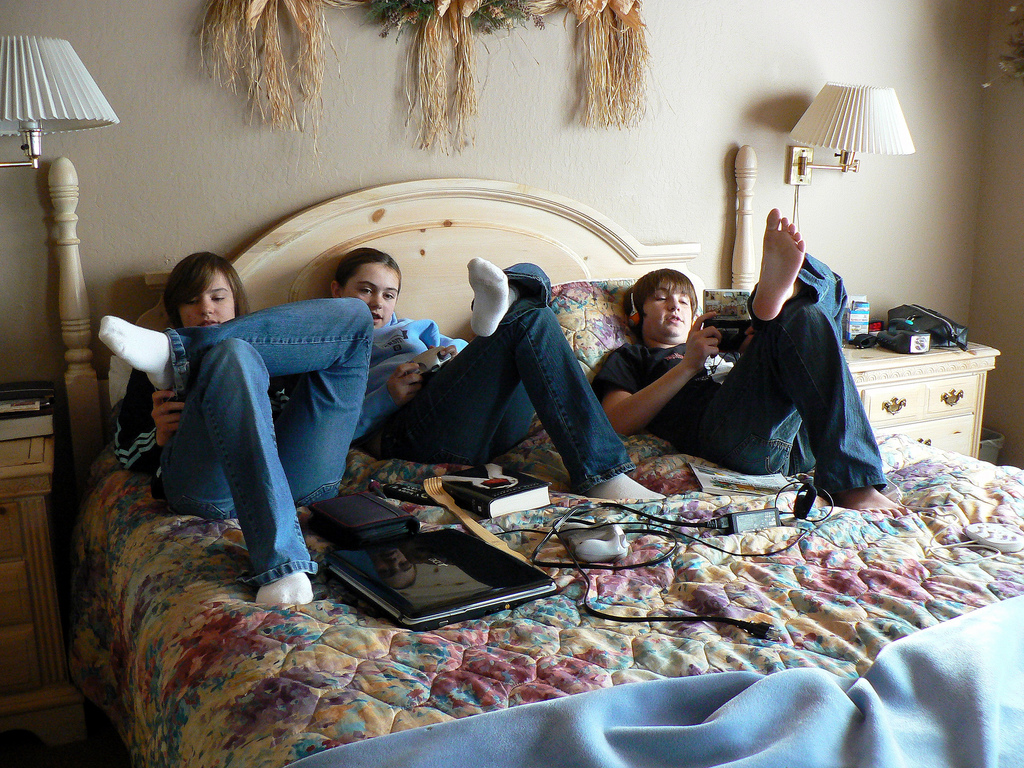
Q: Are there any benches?
A: No, there are no benches.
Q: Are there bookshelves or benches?
A: No, there are no benches or bookshelves.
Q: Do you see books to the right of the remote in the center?
A: Yes, there is a book to the right of the remote.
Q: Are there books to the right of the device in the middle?
A: Yes, there is a book to the right of the remote.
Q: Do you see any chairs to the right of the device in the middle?
A: No, there is a book to the right of the remote.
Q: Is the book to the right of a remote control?
A: Yes, the book is to the right of a remote control.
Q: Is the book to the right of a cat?
A: No, the book is to the right of a remote control.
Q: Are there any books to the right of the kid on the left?
A: Yes, there is a book to the right of the child.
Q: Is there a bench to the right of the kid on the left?
A: No, there is a book to the right of the kid.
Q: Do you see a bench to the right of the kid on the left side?
A: No, there is a book to the right of the kid.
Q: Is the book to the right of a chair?
A: No, the book is to the right of the child.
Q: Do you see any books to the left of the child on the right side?
A: Yes, there is a book to the left of the child.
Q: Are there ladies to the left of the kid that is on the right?
A: No, there is a book to the left of the kid.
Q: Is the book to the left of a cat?
A: No, the book is to the left of the kid.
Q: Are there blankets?
A: Yes, there is a blanket.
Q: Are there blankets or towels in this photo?
A: Yes, there is a blanket.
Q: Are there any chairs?
A: No, there are no chairs.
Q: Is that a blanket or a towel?
A: That is a blanket.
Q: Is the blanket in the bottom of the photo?
A: Yes, the blanket is in the bottom of the image.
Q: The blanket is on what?
A: The blanket is on the bed.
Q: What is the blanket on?
A: The blanket is on the bed.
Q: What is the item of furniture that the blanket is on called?
A: The piece of furniture is a bed.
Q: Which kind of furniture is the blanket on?
A: The blanket is on the bed.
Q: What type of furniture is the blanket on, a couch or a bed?
A: The blanket is on a bed.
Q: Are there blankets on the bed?
A: Yes, there is a blanket on the bed.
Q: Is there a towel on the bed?
A: No, there is a blanket on the bed.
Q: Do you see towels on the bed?
A: No, there is a blanket on the bed.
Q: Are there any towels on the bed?
A: No, there is a blanket on the bed.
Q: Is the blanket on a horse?
A: No, the blanket is on a bed.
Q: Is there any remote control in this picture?
A: Yes, there is a remote control.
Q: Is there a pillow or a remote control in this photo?
A: Yes, there is a remote control.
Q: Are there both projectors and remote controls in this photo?
A: No, there is a remote control but no projectors.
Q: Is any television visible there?
A: No, there are no televisions.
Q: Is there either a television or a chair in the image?
A: No, there are no televisions or chairs.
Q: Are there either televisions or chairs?
A: No, there are no televisions or chairs.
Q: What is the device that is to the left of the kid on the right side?
A: The device is a remote control.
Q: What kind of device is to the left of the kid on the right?
A: The device is a remote control.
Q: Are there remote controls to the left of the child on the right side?
A: Yes, there is a remote control to the left of the child.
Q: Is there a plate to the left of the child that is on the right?
A: No, there is a remote control to the left of the child.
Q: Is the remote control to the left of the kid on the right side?
A: Yes, the remote control is to the left of the kid.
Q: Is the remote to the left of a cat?
A: No, the remote is to the left of the kid.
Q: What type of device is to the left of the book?
A: The device is a remote control.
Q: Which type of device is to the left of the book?
A: The device is a remote control.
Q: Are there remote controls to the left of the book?
A: Yes, there is a remote control to the left of the book.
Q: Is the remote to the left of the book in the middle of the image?
A: Yes, the remote is to the left of the book.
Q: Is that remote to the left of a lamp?
A: No, the remote is to the left of the book.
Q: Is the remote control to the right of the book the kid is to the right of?
A: No, the remote control is to the left of the book.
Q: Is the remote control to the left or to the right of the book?
A: The remote control is to the left of the book.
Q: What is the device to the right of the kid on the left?
A: The device is a remote control.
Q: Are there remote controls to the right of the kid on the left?
A: Yes, there is a remote control to the right of the child.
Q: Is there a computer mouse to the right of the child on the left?
A: No, there is a remote control to the right of the kid.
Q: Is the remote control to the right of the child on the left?
A: Yes, the remote control is to the right of the kid.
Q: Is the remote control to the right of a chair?
A: No, the remote control is to the right of the kid.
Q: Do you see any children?
A: Yes, there is a child.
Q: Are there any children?
A: Yes, there is a child.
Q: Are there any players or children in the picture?
A: Yes, there is a child.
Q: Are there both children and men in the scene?
A: No, there is a child but no men.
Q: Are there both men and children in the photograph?
A: No, there is a child but no men.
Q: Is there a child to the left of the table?
A: Yes, there is a child to the left of the table.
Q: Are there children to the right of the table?
A: No, the child is to the left of the table.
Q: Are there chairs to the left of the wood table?
A: No, there is a child to the left of the table.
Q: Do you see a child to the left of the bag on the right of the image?
A: Yes, there is a child to the left of the bag.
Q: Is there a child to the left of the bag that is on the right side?
A: Yes, there is a child to the left of the bag.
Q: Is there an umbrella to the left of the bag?
A: No, there is a child to the left of the bag.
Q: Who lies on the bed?
A: The kid lies on the bed.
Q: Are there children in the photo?
A: Yes, there is a child.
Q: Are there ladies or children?
A: Yes, there is a child.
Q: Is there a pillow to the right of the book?
A: No, there is a child to the right of the book.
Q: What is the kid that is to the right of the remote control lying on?
A: The kid is lying on the bed.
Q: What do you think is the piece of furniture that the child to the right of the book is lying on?
A: The piece of furniture is a bed.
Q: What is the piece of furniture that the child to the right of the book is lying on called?
A: The piece of furniture is a bed.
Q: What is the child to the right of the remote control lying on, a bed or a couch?
A: The child is lying on a bed.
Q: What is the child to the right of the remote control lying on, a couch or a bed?
A: The child is lying on a bed.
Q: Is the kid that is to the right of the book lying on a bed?
A: Yes, the child is lying on a bed.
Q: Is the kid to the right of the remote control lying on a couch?
A: No, the kid is lying on a bed.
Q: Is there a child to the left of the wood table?
A: Yes, there is a child to the left of the table.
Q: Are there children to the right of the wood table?
A: No, the child is to the left of the table.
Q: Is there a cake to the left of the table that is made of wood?
A: No, there is a child to the left of the table.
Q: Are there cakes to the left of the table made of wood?
A: No, there is a child to the left of the table.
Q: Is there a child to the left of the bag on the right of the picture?
A: Yes, there is a child to the left of the bag.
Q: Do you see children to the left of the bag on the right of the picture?
A: Yes, there is a child to the left of the bag.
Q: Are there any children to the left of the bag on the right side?
A: Yes, there is a child to the left of the bag.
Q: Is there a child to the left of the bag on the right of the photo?
A: Yes, there is a child to the left of the bag.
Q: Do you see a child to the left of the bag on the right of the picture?
A: Yes, there is a child to the left of the bag.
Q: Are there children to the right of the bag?
A: No, the child is to the left of the bag.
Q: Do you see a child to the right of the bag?
A: No, the child is to the left of the bag.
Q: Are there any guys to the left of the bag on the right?
A: No, there is a child to the left of the bag.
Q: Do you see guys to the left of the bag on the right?
A: No, there is a child to the left of the bag.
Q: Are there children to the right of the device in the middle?
A: Yes, there is a child to the right of the remote.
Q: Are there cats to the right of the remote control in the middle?
A: No, there is a child to the right of the remote control.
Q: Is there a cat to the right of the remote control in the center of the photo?
A: No, there is a child to the right of the remote control.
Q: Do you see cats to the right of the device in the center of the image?
A: No, there is a child to the right of the remote control.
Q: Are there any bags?
A: Yes, there is a bag.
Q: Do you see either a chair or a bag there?
A: Yes, there is a bag.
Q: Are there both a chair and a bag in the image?
A: No, there is a bag but no chairs.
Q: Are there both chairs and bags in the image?
A: No, there is a bag but no chairs.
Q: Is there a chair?
A: No, there are no chairs.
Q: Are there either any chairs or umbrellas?
A: No, there are no chairs or umbrellas.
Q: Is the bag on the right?
A: Yes, the bag is on the right of the image.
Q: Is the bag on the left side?
A: No, the bag is on the right of the image.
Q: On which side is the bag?
A: The bag is on the right of the image.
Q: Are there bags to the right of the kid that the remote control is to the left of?
A: Yes, there is a bag to the right of the child.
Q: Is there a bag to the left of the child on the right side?
A: No, the bag is to the right of the child.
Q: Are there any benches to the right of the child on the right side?
A: No, there is a bag to the right of the kid.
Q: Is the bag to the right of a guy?
A: No, the bag is to the right of a child.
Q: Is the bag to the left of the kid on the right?
A: No, the bag is to the right of the kid.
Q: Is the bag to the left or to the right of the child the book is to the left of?
A: The bag is to the right of the child.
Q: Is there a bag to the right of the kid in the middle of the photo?
A: Yes, there is a bag to the right of the child.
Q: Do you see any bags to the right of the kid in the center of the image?
A: Yes, there is a bag to the right of the child.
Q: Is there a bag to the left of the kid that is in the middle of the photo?
A: No, the bag is to the right of the child.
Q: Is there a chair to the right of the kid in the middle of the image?
A: No, there is a bag to the right of the child.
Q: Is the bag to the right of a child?
A: Yes, the bag is to the right of a child.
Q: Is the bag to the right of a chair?
A: No, the bag is to the right of a child.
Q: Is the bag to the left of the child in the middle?
A: No, the bag is to the right of the child.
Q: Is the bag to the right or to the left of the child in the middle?
A: The bag is to the right of the kid.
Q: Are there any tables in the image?
A: Yes, there is a table.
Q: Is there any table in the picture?
A: Yes, there is a table.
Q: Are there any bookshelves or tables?
A: Yes, there is a table.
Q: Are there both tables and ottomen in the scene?
A: No, there is a table but no ottomen.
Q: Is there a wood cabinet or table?
A: Yes, there is a wood table.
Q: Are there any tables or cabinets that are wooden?
A: Yes, the table is wooden.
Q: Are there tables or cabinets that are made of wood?
A: Yes, the table is made of wood.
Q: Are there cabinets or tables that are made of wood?
A: Yes, the table is made of wood.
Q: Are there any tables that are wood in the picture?
A: Yes, there is a wood table.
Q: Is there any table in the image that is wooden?
A: Yes, there is a table that is wooden.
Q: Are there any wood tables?
A: Yes, there is a table that is made of wood.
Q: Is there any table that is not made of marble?
A: Yes, there is a table that is made of wood.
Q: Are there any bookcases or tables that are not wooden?
A: No, there is a table but it is wooden.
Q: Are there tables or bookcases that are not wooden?
A: No, there is a table but it is wooden.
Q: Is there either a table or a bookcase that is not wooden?
A: No, there is a table but it is wooden.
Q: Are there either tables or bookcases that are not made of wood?
A: No, there is a table but it is made of wood.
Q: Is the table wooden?
A: Yes, the table is wooden.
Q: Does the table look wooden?
A: Yes, the table is wooden.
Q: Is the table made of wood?
A: Yes, the table is made of wood.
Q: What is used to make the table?
A: The table is made of wood.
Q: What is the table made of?
A: The table is made of wood.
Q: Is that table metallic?
A: No, the table is wooden.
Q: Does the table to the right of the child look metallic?
A: No, the table is wooden.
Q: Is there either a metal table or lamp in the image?
A: No, there is a table but it is wooden.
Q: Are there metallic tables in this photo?
A: No, there is a table but it is wooden.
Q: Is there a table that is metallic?
A: No, there is a table but it is wooden.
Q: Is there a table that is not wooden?
A: No, there is a table but it is wooden.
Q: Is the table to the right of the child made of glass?
A: No, the table is made of wood.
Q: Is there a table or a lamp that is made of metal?
A: No, there is a table but it is made of wood.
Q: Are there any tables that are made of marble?
A: No, there is a table but it is made of wood.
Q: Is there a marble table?
A: No, there is a table but it is made of wood.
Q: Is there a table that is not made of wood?
A: No, there is a table but it is made of wood.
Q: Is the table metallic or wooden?
A: The table is wooden.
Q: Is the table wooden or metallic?
A: The table is wooden.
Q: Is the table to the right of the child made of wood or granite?
A: The table is made of wood.